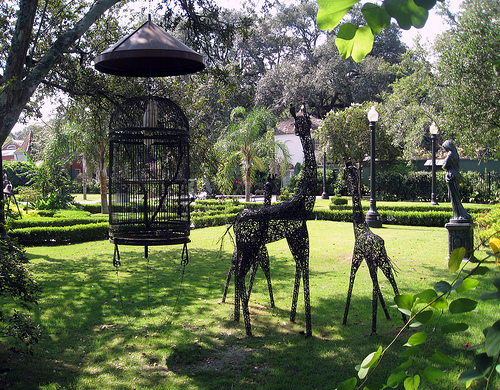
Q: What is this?
A: Cage.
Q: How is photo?
A: Clear.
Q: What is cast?
A: Shadow.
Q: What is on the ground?
A: Grass.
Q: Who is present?
A: No one.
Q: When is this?
A: Daytime.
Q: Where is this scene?
A: At a park.